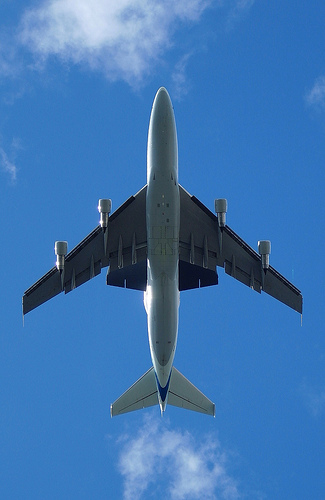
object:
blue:
[0, 0, 325, 499]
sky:
[0, 0, 325, 499]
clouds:
[305, 76, 324, 107]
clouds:
[0, 144, 19, 187]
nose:
[151, 85, 171, 105]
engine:
[53, 238, 68, 277]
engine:
[256, 237, 274, 268]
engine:
[212, 196, 229, 230]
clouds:
[105, 403, 239, 498]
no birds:
[0, 0, 325, 499]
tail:
[107, 367, 162, 420]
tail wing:
[19, 183, 148, 317]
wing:
[178, 183, 308, 313]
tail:
[165, 366, 219, 420]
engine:
[96, 195, 116, 235]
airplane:
[22, 82, 305, 420]